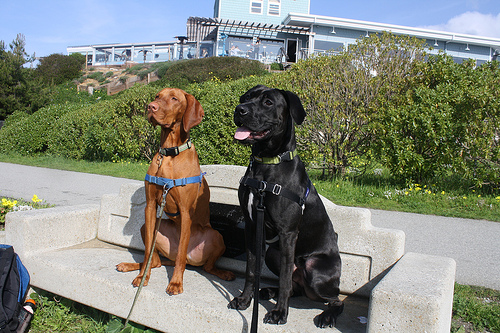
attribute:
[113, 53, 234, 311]
dog — black, shorthaired, brown, sitting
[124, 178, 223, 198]
harness — blue, attacthed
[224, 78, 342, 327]
dog — black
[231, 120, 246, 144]
tongue — pink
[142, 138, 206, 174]
collar — canvas, green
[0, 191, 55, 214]
flower — blooming, yellow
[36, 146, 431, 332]
bench — cement, concrete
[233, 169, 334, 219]
harness — black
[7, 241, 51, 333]
backpack — blue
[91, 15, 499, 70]
building — large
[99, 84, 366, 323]
dogs — sitting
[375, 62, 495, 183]
bush — green